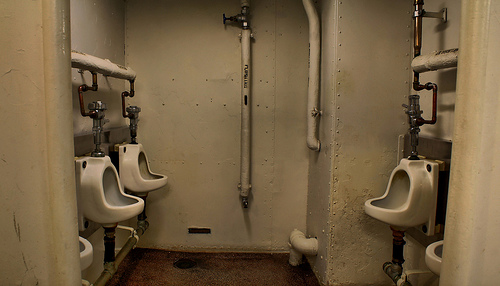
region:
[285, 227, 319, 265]
a white pipe running into the floor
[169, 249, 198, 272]
a drain in a floor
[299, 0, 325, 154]
a white pipe running down a wall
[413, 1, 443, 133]
a metal pipe running to a toilet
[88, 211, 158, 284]
a pipe connecting urinals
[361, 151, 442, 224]
a white urinal on a wall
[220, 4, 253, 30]
a faucet handle on a pipe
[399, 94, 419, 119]
a flush handle on a urinal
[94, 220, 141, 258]
a white connector attached to a pipe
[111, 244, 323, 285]
a dirty floor under urinals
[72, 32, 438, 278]
urinals in a bleak room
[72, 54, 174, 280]
collection of pipes running from urinal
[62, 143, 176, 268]
white urinals in a line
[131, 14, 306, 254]
dingy grey metal wall with rivets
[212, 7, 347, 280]
pipes coming out of the wall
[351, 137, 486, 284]
two urinals side by side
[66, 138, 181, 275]
three urinals in a row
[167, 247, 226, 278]
drain in the floor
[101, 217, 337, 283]
dark and dirty looking floor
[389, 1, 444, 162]
pipes running down to urinal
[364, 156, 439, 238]
White urinal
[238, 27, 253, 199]
White water pipe on the wall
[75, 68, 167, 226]
Two urinals side by side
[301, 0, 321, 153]
White pipe attached to the wall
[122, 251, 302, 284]
Brown colored floor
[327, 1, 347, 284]
Rivets on the wall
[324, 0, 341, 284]
Corner of the wall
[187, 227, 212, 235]
Hole in the wall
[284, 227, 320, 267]
Pipe attached to the floor and the wall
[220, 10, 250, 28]
Wall pipe valve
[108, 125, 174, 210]
The urinal is white.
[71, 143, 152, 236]
The urinal is white.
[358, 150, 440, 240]
The urinal is white.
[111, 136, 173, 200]
The urinal is porcelain.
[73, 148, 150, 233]
The urinal is porcelain.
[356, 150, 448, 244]
The urinal is porcelain.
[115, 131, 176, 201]
The urinal is vacant.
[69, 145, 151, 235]
The urinal is vacant.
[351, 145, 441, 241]
The urinal is vacant.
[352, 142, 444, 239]
The urinal is available.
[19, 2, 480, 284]
a bathroom with urirnals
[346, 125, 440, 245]
this is a urinal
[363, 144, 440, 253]
the urinal is white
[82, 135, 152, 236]
the urinal is L shaped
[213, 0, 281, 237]
pipe in middle of wall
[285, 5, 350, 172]
pipe on side of wall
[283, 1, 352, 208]
the pipe is white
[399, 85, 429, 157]
silver plumbing connected to urinal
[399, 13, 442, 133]
brass pipe plumbing connection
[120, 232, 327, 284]
floor is dark brown